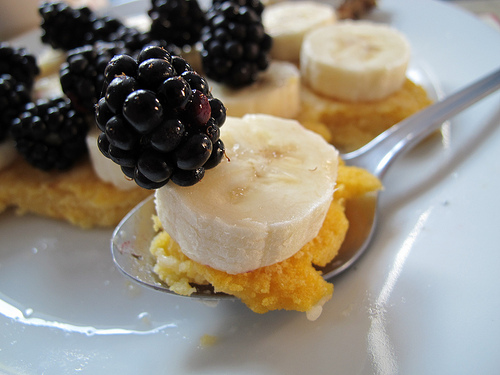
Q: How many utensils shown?
A: 1.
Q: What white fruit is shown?
A: Bananas.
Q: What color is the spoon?
A: Silver.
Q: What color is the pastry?
A: Yellow.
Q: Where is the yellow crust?
A: On the spoon.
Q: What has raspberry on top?
A: Banana.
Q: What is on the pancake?
A: A banana slice.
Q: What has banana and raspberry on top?
A: Pancake.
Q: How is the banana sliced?
A: Thick.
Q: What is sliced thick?
A: Banana.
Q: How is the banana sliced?
A: Thick.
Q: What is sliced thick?
A: Banana.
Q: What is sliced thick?
A: Banana.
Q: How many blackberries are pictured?
A: Eight.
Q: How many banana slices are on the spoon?
A: One.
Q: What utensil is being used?
A: Spoon.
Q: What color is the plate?
A: White.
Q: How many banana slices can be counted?
A: Five.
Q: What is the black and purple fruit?
A: Blackberry.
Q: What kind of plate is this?
A: Porcelain.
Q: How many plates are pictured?
A: One.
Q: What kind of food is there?
A: Dessert.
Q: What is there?
A: Food.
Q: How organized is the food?
A: Very organized.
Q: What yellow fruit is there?
A: Banana.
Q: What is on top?
A: Blackberries.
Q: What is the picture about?
A: Dessert.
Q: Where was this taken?
A: Table.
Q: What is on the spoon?
A: Blackberry banana cake.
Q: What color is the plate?
A: White.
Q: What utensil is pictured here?
A: Spoon.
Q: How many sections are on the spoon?
A: 3.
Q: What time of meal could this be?
A: Breakfast.